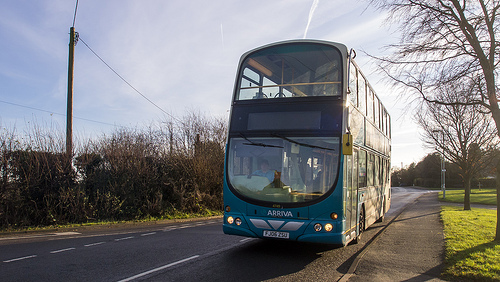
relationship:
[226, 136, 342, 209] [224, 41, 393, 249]
window on bus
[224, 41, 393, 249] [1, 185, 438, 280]
bus on road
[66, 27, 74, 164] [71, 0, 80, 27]
pole has wire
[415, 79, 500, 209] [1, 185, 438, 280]
tree near road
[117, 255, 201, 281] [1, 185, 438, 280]
line on road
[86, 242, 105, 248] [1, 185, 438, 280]
line on road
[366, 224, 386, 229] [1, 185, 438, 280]
shadow on road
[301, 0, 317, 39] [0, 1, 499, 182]
line in sky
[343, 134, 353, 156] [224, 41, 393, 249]
mirror on bus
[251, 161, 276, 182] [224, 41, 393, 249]
man driving bus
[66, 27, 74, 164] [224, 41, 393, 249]
pole near bus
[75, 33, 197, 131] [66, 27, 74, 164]
line on pole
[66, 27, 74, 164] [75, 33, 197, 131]
pole has line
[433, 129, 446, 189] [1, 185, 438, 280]
street light near road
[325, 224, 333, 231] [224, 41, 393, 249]
light on bus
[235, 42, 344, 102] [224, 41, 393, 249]
window on bus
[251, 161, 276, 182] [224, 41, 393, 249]
man on bus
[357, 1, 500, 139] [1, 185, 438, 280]
tree near road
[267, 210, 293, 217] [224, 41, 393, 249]
arriva on bus